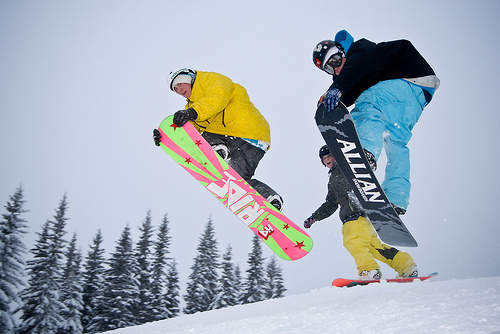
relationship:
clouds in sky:
[0, 0, 500, 229] [1, 1, 498, 293]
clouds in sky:
[0, 0, 500, 229] [67, 24, 129, 81]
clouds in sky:
[0, 0, 500, 229] [164, 15, 238, 60]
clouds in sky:
[274, 85, 302, 105] [1, 1, 498, 293]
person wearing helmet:
[167, 65, 283, 211] [168, 66, 195, 88]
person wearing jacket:
[167, 65, 287, 215] [191, 68, 272, 146]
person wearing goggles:
[309, 20, 438, 215] [321, 44, 340, 76]